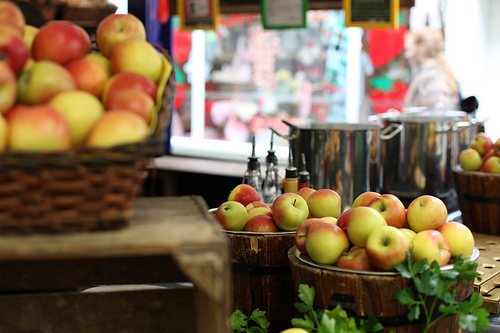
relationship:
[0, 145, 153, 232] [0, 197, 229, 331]
basket on table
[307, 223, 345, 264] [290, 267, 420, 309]
apple in a barrel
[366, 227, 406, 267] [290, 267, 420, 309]
apple in a barrel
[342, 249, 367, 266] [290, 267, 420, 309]
apple in a barrel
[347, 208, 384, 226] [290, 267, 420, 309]
apple in a barrel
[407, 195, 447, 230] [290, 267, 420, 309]
apple in a barrel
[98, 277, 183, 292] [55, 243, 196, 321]
space between wood